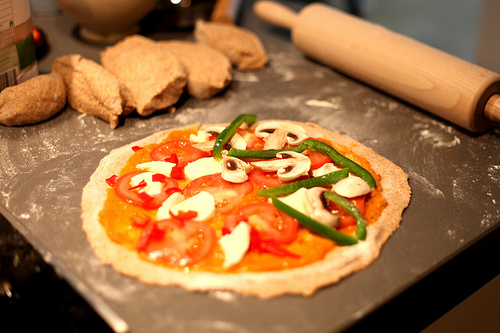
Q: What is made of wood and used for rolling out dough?
A: The rolling pin.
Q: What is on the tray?
A: A pizza.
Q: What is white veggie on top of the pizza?
A: Mushrooms.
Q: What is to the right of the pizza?
A: Unrolled dough.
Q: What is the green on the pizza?
A: Green bell peppers.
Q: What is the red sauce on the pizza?
A: Tomato sauce.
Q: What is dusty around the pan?
A: The flour.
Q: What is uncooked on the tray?
A: The pizza.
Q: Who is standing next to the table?
A: Nobody.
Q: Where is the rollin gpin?
A: Table.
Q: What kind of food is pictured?
A: Pizza.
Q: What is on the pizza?
A: Toppings.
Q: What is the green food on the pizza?
A: Peppers.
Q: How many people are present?
A: 0.